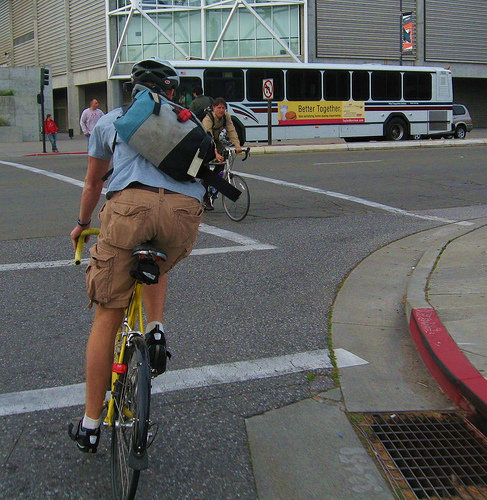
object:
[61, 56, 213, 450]
man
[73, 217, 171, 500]
bike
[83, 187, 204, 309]
shorts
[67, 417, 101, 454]
shoe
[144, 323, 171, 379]
shoe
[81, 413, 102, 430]
sock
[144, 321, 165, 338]
sock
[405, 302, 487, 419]
curb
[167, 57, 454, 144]
bus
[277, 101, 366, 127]
sign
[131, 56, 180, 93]
helmet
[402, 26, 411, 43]
dog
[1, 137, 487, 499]
road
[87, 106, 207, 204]
shirt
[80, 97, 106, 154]
man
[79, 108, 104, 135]
sweatshirt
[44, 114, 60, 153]
woman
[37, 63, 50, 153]
pole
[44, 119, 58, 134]
sweatshirt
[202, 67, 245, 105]
window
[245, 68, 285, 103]
window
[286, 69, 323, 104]
window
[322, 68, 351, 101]
window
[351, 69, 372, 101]
window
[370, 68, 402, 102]
window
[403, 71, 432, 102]
window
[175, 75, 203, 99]
window